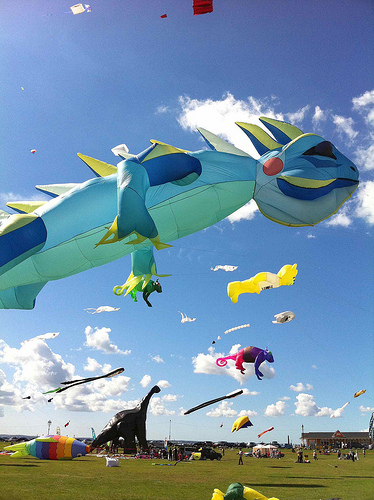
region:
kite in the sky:
[41, 356, 132, 412]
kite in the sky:
[202, 313, 259, 352]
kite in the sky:
[207, 327, 280, 384]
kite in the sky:
[190, 385, 247, 418]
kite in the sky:
[250, 416, 281, 440]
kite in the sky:
[326, 374, 370, 424]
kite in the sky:
[0, 97, 352, 347]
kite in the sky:
[21, 126, 57, 163]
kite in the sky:
[15, 84, 42, 99]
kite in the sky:
[62, 7, 93, 18]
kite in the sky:
[162, 298, 211, 339]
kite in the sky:
[197, 261, 252, 285]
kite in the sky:
[226, 253, 314, 300]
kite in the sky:
[345, 381, 366, 400]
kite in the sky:
[64, 3, 95, 30]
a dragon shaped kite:
[34, 90, 371, 287]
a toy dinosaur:
[94, 361, 172, 460]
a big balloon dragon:
[66, 104, 321, 332]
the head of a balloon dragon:
[160, 109, 370, 278]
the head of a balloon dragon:
[223, 84, 368, 220]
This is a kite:
[227, 242, 310, 306]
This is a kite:
[108, 136, 191, 335]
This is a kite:
[183, 370, 266, 420]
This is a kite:
[225, 393, 258, 442]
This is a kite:
[255, 414, 278, 450]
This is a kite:
[336, 375, 372, 415]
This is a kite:
[265, 299, 303, 329]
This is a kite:
[208, 341, 289, 389]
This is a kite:
[206, 317, 262, 345]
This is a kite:
[21, 355, 158, 412]